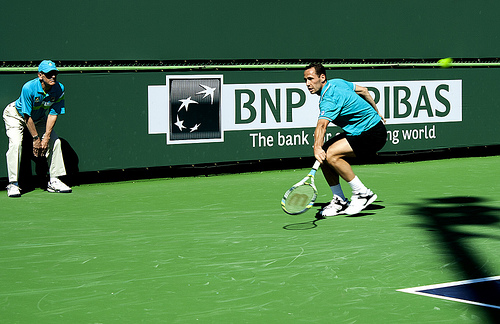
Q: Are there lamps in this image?
A: No, there are no lamps.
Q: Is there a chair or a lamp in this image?
A: No, there are no lamps or chairs.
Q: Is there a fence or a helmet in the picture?
A: No, there are no helmets or fences.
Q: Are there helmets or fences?
A: No, there are no helmets or fences.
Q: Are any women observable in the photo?
A: No, there are no women.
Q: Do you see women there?
A: No, there are no women.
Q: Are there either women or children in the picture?
A: No, there are no women or children.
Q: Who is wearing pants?
A: The man is wearing pants.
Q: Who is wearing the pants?
A: The man is wearing pants.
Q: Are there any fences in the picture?
A: No, there are no fences.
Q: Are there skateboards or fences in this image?
A: No, there are no fences or skateboards.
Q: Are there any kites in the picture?
A: No, there are no kites.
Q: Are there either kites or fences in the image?
A: No, there are no kites or fences.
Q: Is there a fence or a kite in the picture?
A: No, there are no kites or fences.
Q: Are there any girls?
A: No, there are no girls.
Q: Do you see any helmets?
A: No, there are no helmets.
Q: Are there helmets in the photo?
A: No, there are no helmets.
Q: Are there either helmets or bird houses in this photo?
A: No, there are no helmets or bird houses.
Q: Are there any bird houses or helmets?
A: No, there are no helmets or bird houses.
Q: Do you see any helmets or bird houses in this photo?
A: No, there are no helmets or bird houses.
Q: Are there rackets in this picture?
A: Yes, there is a racket.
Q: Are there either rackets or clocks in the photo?
A: Yes, there is a racket.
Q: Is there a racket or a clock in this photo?
A: Yes, there is a racket.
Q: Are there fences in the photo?
A: No, there are no fences.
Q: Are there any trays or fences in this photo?
A: No, there are no fences or trays.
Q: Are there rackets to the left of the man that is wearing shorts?
A: Yes, there is a racket to the left of the man.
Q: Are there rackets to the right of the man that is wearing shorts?
A: No, the racket is to the left of the man.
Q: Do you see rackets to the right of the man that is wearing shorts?
A: No, the racket is to the left of the man.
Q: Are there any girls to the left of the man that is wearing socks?
A: No, there is a racket to the left of the man.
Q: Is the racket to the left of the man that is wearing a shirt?
A: Yes, the racket is to the left of the man.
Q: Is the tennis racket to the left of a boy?
A: No, the tennis racket is to the left of the man.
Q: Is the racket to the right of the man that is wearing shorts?
A: No, the racket is to the left of the man.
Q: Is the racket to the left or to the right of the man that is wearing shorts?
A: The racket is to the left of the man.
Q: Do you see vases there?
A: No, there are no vases.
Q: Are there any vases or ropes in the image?
A: No, there are no vases or ropes.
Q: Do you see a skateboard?
A: No, there are no skateboards.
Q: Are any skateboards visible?
A: No, there are no skateboards.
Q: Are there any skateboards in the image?
A: No, there are no skateboards.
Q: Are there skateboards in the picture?
A: No, there are no skateboards.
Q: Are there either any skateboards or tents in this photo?
A: No, there are no skateboards or tents.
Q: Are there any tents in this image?
A: No, there are no tents.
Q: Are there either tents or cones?
A: No, there are no tents or cones.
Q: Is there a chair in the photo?
A: No, there are no chairs.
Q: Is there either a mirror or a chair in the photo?
A: No, there are no chairs or mirrors.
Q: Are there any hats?
A: Yes, there is a hat.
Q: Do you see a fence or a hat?
A: Yes, there is a hat.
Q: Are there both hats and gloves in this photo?
A: No, there is a hat but no gloves.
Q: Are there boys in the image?
A: No, there are no boys.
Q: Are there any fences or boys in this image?
A: No, there are no boys or fences.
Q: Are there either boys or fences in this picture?
A: No, there are no boys or fences.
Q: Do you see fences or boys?
A: No, there are no boys or fences.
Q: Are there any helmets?
A: No, there are no helmets.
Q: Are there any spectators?
A: No, there are no spectators.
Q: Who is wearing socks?
A: The man is wearing socks.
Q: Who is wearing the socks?
A: The man is wearing socks.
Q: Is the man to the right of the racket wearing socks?
A: Yes, the man is wearing socks.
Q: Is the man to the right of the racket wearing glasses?
A: No, the man is wearing socks.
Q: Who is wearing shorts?
A: The man is wearing shorts.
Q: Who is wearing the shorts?
A: The man is wearing shorts.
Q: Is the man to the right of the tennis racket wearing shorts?
A: Yes, the man is wearing shorts.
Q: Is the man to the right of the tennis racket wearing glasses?
A: No, the man is wearing shorts.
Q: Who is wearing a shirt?
A: The man is wearing a shirt.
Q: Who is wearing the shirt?
A: The man is wearing a shirt.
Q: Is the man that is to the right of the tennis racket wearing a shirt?
A: Yes, the man is wearing a shirt.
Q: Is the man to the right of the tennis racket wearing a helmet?
A: No, the man is wearing a shirt.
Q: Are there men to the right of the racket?
A: Yes, there is a man to the right of the racket.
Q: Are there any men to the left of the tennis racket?
A: No, the man is to the right of the tennis racket.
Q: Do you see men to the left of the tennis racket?
A: No, the man is to the right of the tennis racket.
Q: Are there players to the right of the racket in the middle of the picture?
A: No, there is a man to the right of the racket.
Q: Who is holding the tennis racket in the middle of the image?
A: The man is holding the racket.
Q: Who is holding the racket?
A: The man is holding the racket.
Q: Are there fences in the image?
A: No, there are no fences.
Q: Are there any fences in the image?
A: No, there are no fences.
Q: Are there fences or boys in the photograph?
A: No, there are no fences or boys.